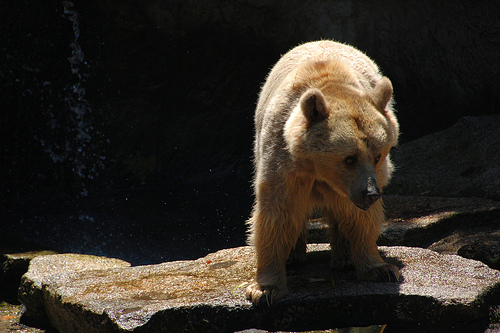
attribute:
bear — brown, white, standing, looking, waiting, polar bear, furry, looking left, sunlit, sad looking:
[237, 38, 406, 311]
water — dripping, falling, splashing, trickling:
[25, 0, 115, 250]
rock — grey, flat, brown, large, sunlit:
[20, 242, 499, 332]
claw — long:
[385, 269, 394, 285]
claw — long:
[269, 286, 279, 305]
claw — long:
[263, 289, 273, 310]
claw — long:
[389, 265, 402, 285]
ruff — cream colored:
[283, 80, 396, 191]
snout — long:
[347, 174, 381, 213]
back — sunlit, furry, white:
[253, 39, 392, 111]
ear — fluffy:
[367, 74, 394, 111]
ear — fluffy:
[299, 87, 330, 126]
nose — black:
[363, 183, 383, 203]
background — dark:
[2, 0, 499, 275]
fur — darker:
[294, 57, 381, 129]